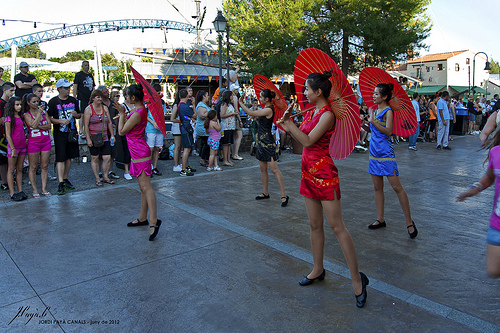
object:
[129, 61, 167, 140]
umbrella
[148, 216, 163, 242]
shoe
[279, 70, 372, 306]
woman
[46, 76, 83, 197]
man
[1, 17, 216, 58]
arch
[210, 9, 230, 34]
light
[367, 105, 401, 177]
skirt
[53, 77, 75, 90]
cap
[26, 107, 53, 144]
tank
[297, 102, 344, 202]
dress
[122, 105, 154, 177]
outfit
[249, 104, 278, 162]
flapper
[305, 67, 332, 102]
hair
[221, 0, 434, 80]
tree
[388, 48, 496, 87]
building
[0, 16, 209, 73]
wire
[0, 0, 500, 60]
sky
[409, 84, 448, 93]
awning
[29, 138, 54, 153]
shorts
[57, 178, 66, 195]
sneaker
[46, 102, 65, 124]
arm